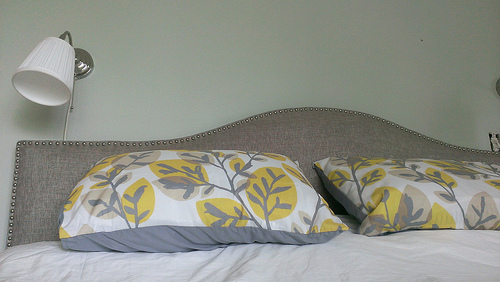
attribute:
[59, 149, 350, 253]
pillow — resting, colorful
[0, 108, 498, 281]
bed — large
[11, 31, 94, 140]
lamp — metal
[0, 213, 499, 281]
sheet — white, blanket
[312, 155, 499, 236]
pillow — one of two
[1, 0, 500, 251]
wall — white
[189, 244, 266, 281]
lump — white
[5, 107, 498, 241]
headboard — textured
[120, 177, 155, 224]
leaf — yellow, grey, printed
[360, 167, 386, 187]
leaf — yellow, grey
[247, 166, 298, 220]
leaf — yellow, grey